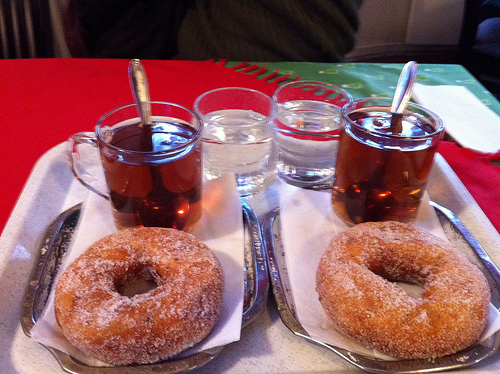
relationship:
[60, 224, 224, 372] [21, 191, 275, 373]
doughnut on plate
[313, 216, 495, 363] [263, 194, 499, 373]
doughnut on plate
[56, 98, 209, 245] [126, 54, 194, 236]
glass has spoon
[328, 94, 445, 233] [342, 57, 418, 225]
glass has spoon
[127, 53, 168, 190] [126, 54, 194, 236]
handle of spoon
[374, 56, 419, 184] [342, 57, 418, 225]
handle of spoon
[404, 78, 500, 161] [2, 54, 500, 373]
napkin lying on table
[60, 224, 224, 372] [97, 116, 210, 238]
doughnut with tea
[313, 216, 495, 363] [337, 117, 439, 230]
doughnut with tea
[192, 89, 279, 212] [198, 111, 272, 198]
glass filled with water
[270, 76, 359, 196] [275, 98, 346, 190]
glass filled with water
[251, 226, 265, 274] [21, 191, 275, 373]
writing on side of plate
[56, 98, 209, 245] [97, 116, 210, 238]
glass has tea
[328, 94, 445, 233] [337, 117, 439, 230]
glass has tea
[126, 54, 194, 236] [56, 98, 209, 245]
spoon in glass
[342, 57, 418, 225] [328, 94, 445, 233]
spoon in glass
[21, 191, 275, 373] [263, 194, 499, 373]
plate identical to plate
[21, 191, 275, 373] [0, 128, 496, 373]
plate on a tray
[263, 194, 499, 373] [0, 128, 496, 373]
plate on a tray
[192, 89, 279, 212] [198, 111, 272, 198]
glass of water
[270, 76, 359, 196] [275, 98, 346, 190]
glass of water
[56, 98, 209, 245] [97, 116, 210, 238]
glass of tea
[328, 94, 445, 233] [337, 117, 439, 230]
glass of tea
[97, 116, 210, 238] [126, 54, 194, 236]
tea with spoon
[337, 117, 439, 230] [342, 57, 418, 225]
tea with spoon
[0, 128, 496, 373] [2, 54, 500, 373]
tray on table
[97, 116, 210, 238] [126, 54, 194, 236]
tea with a spoon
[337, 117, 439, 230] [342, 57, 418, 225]
tea with a spoon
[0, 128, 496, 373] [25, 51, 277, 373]
tray has meal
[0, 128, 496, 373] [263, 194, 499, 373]
tray has meal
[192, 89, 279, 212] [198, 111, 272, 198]
glass with water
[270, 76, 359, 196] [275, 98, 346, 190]
glass with water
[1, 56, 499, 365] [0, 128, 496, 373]
table cloth under tray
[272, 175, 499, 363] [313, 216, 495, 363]
napkin under doughnut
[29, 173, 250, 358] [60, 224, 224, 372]
napkin under doughnut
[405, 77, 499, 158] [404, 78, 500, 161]
stack of napkin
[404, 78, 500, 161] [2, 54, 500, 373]
napkin near edge of table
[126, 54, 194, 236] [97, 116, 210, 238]
spoon for stirring tea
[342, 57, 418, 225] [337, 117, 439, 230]
spoon for stirring tea